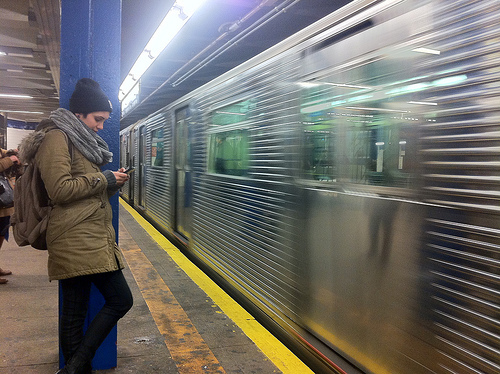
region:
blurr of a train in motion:
[101, 0, 489, 371]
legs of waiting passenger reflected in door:
[323, 167, 407, 287]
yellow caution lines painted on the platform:
[117, 197, 312, 370]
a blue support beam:
[43, 0, 140, 372]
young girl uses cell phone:
[11, 84, 140, 282]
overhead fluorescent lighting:
[88, 6, 229, 99]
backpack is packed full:
[1, 142, 47, 268]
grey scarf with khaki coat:
[6, 101, 128, 278]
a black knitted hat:
[61, 63, 115, 125]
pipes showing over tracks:
[54, 0, 306, 120]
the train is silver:
[121, 112, 320, 334]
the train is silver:
[178, 52, 376, 352]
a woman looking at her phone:
[58, 89, 144, 321]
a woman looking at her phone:
[38, 64, 180, 365]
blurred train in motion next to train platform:
[110, 3, 494, 366]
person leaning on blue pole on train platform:
[13, 66, 140, 373]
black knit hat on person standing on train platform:
[61, 70, 116, 120]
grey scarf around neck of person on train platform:
[13, 101, 115, 176]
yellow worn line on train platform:
[111, 225, 230, 372]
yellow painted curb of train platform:
[113, 193, 318, 371]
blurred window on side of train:
[194, 88, 269, 183]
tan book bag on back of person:
[3, 144, 52, 252]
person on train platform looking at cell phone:
[10, 72, 145, 372]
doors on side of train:
[161, 97, 208, 243]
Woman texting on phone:
[13, 77, 134, 372]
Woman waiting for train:
[11, 77, 137, 372]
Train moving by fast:
[114, 2, 499, 361]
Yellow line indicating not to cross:
[118, 194, 315, 372]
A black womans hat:
[66, 75, 120, 119]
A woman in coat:
[19, 110, 128, 280]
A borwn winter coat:
[32, 124, 130, 268]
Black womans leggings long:
[48, 250, 137, 365]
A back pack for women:
[8, 154, 49, 251]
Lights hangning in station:
[121, 0, 209, 115]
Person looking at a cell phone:
[9, 70, 138, 372]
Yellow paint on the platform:
[117, 191, 313, 371]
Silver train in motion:
[120, 0, 497, 371]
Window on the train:
[197, 98, 261, 179]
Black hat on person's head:
[67, 70, 114, 140]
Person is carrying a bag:
[7, 76, 130, 253]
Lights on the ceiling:
[116, 0, 210, 102]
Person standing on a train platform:
[1, 72, 308, 372]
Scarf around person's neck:
[46, 101, 116, 166]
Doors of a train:
[294, 1, 433, 371]